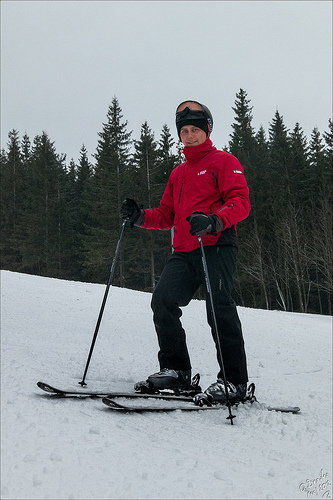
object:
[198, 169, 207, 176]
logo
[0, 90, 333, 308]
trees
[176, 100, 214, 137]
hat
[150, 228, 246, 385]
pants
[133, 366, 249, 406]
shoes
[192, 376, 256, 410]
ski boot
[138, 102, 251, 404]
women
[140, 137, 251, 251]
jacket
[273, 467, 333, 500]
logo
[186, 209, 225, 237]
logo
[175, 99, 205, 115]
goggles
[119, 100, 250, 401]
man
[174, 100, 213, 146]
head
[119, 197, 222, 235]
gloves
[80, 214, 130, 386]
stick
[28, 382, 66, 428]
logo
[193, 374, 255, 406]
boot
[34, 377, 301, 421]
skies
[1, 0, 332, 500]
background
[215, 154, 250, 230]
sleeve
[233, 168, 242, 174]
logo